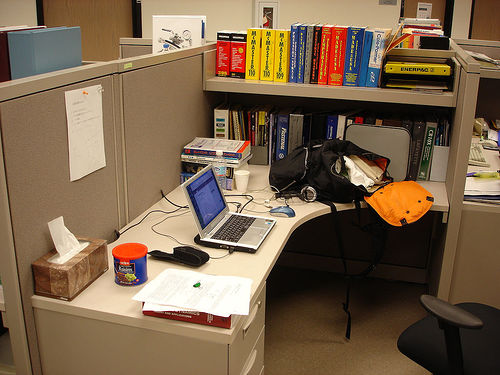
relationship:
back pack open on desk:
[259, 137, 440, 236] [39, 143, 456, 333]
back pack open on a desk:
[268, 137, 436, 342] [28, 159, 450, 373]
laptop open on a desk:
[180, 162, 277, 255] [28, 159, 450, 373]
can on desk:
[111, 240, 148, 286] [31, 163, 448, 344]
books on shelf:
[238, 35, 443, 105] [228, 7, 498, 184]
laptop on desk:
[182, 161, 279, 250] [28, 159, 450, 373]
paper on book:
[145, 279, 245, 314] [152, 302, 235, 333]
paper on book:
[131, 266, 252, 317] [152, 302, 235, 333]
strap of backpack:
[326, 196, 375, 348] [267, 136, 431, 341]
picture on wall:
[259, 1, 279, 27] [2, 4, 484, 71]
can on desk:
[104, 237, 159, 290] [28, 159, 450, 373]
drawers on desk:
[227, 278, 265, 373] [28, 159, 450, 373]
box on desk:
[29, 235, 111, 310] [37, 68, 477, 373]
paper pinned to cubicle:
[58, 80, 116, 187] [10, 150, 457, 374]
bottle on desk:
[205, 145, 225, 180] [70, 162, 433, 375]